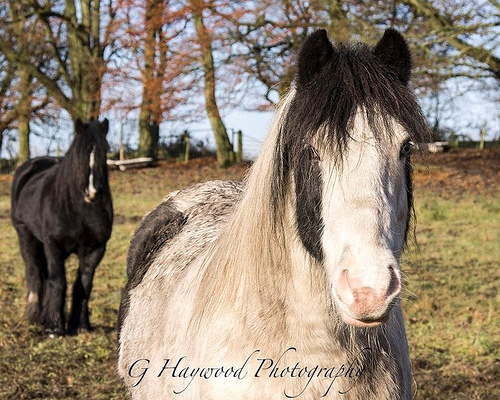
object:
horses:
[8, 116, 114, 336]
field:
[0, 141, 499, 399]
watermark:
[124, 346, 377, 398]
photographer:
[127, 344, 377, 399]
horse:
[111, 28, 433, 400]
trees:
[0, 0, 66, 175]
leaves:
[158, 10, 166, 20]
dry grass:
[0, 147, 499, 399]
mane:
[285, 62, 432, 149]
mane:
[80, 125, 112, 146]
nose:
[341, 264, 396, 321]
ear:
[294, 26, 335, 86]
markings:
[113, 199, 188, 349]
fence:
[0, 128, 260, 162]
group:
[0, 0, 242, 175]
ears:
[71, 116, 85, 134]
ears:
[372, 23, 414, 83]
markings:
[85, 173, 98, 198]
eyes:
[395, 134, 417, 160]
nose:
[84, 181, 103, 198]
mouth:
[328, 295, 404, 325]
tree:
[165, 0, 276, 168]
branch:
[235, 20, 280, 42]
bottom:
[368, 386, 380, 396]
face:
[73, 130, 111, 207]